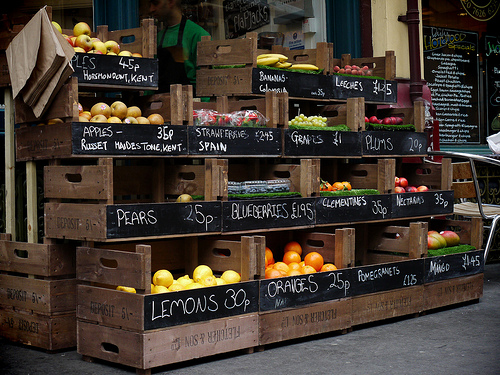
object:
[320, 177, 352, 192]
clementines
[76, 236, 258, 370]
bin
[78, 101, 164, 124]
apples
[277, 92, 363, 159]
bin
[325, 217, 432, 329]
box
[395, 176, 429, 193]
ground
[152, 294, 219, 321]
word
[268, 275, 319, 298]
word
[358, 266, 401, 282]
word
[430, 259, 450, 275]
word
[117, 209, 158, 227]
word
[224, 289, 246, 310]
numbers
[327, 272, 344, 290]
numbers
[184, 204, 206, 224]
numbers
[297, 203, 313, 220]
numbers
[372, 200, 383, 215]
numbers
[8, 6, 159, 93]
bins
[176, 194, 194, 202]
pear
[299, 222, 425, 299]
box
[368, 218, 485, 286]
box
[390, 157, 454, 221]
box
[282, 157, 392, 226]
box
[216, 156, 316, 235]
box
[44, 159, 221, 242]
box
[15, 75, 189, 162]
box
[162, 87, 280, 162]
box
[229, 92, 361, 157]
box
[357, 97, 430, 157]
box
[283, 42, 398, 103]
box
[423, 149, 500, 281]
chair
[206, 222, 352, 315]
bin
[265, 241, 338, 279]
fruit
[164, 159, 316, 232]
box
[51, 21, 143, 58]
apples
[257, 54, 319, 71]
bananas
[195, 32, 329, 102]
bin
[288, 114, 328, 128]
grapes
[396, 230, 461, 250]
fruits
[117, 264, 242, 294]
fruits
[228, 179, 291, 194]
fruits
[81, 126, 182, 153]
names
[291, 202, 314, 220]
prices